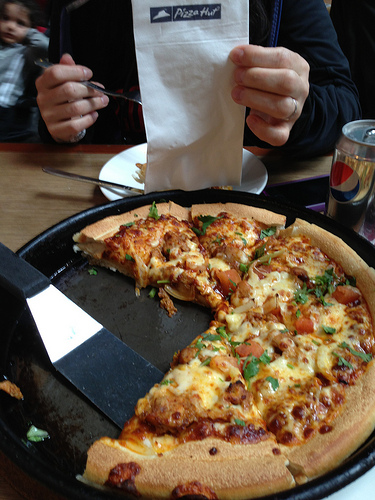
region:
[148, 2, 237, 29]
Pizza Hut logo on napkin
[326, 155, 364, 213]
Pepsi ball logo on can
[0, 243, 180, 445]
black and silver pizza server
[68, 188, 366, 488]
Cheesy pizza with tomatoes and herbs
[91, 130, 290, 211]
small white plate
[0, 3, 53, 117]
small child looking on in background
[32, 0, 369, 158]
person in sweatshirt holding up a napkin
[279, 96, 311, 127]
thin gold wedding band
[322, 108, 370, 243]
silver Diet Pepsi can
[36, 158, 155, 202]
silver knife resting on plate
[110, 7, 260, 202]
person holds white receipt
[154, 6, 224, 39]
black writing on receipt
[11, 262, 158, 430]
steel spatula in pizza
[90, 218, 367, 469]
brown crust on pizza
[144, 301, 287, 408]
yellow cheese on pizza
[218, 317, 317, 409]
orange tomatoes on pizza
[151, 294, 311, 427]
green vegetables on pizza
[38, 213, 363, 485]
pizza in black pan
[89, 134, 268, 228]
knife on white plate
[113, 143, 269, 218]
plate on brown table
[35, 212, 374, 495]
a pizza sitting on the tray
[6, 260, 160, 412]
a spatula to pick up the pizza slices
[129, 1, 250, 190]
the paper the man is holding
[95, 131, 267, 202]
the plate with food on the table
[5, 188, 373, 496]
the tray the pizza is sitting on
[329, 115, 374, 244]
a can of soda sitting on the table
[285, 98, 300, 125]
the wedding ring on the man's hand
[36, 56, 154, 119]
the fork in the man's hand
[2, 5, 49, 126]
a little kid looking all bored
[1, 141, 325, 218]
the table the food is sitting on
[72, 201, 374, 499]
Pizza with 2 slices missing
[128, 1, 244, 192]
Pizza Hut napkin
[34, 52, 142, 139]
Person's hand holding silverware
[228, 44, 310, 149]
Person's hand wearing a wedding ring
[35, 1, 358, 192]
Person holding a white paper napkin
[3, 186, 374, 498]
Pizza in a round black serving dish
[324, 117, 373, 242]
Open can of soda pop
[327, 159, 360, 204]
Pepsi logo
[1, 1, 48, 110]
Seated child slightly out of focus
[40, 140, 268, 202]
Silverware resting on a white plate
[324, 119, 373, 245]
Can of Diet Pepsi on the table.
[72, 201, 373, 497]
Six slices of pizza left on the platter.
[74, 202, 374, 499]
Cheese pizza with some tomatoes and greens.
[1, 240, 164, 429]
Spatula used for picking up the pizza.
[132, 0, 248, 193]
Napkin with a Pizza Hut logo at the top.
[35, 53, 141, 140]
Man eating his pizza with a fork.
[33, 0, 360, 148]
Man in black jacket holding fork.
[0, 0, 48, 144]
Child standing behind the man staring at the camera.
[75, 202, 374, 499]
Several slices are missing from the pizza.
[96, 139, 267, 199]
Food is lying on the man's plate.